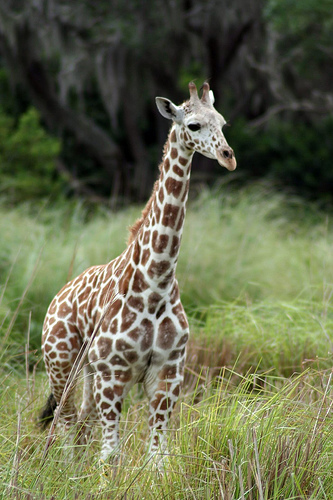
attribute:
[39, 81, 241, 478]
giraffe — white, brown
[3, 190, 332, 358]
weeds — tall, dried, green, brown, bright green, large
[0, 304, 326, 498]
grass — tall, green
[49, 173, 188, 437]
spots — brown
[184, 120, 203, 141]
eye — black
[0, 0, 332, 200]
trees — leafless, ghostly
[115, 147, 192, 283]
neck — long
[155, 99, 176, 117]
ear — long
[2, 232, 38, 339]
bud — green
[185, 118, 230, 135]
eyes — large, black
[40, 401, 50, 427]
hair — black